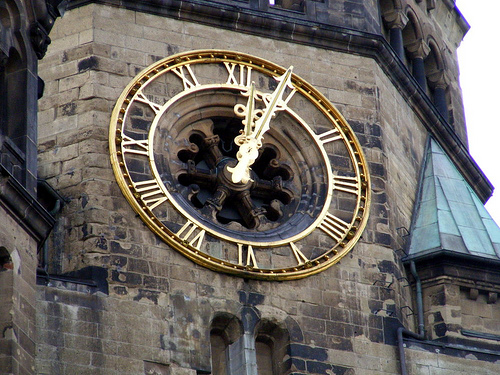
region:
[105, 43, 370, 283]
a clock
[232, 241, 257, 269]
roman numerial on the clock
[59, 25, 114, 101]
the building is made of bricks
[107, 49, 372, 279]
the clock is gold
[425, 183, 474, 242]
the bricks are blue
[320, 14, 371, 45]
the bricks are black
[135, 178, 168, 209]
the roman numerial is gold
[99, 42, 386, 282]
a clock on the building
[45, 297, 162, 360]
the building has bricks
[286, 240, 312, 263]
the numbers are gold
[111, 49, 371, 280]
the clock has hands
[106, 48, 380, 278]
the clock has Roman numerals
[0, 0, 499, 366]
the building has bricks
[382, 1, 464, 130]
the building has arches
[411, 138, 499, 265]
the roof is green and grey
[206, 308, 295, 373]
the windows are curved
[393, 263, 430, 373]
the pipes are grey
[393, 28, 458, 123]
the pillars are dark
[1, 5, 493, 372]
the clock is on the building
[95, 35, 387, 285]
clock on a brick wall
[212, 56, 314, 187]
hour and minute hand of a clock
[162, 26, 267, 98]
roman numerals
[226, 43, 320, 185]
tick of a clock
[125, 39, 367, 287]
roman numeral on a clock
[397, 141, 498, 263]
roof of a building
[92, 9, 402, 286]
analog clock on wall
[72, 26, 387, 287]
a clock on a tower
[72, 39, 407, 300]
a fancy clock on a wall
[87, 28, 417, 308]
a fancy building with a clock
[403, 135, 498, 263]
sectioned green slanted roof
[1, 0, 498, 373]
light brown brick tower building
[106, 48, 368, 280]
gold colored metal clock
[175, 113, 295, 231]
scalloped cut out in the clock face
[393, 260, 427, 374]
green drainage pipe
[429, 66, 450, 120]
black and gold column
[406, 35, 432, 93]
black and gold column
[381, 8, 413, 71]
black and gold column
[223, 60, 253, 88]
gold xii signifying the 12 o'clock position on the clock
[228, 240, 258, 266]
gold vi signifying the 6 o'clock position on the clock